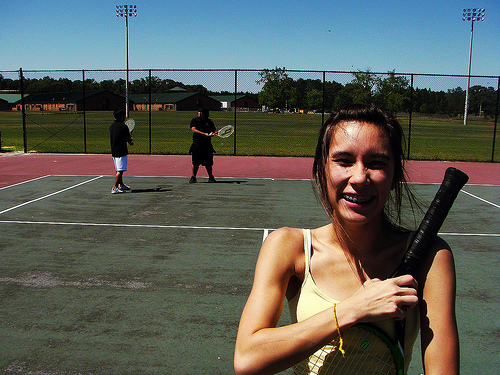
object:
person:
[107, 109, 135, 194]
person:
[188, 106, 218, 184]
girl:
[233, 103, 461, 375]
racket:
[276, 166, 469, 374]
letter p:
[359, 337, 371, 350]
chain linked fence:
[0, 69, 500, 161]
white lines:
[0, 219, 500, 237]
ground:
[0, 153, 499, 375]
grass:
[1, 110, 499, 161]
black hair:
[311, 103, 432, 271]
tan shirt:
[288, 228, 422, 375]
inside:
[293, 322, 403, 374]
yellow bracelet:
[332, 301, 346, 356]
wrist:
[328, 300, 364, 330]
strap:
[303, 227, 312, 275]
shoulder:
[266, 223, 334, 277]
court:
[0, 162, 500, 374]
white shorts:
[111, 155, 128, 171]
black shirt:
[108, 120, 131, 158]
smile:
[340, 191, 380, 212]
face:
[323, 120, 395, 224]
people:
[107, 109, 136, 195]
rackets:
[119, 117, 137, 133]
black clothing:
[188, 117, 216, 167]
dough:
[0, 146, 17, 152]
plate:
[0, 145, 15, 154]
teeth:
[345, 195, 374, 204]